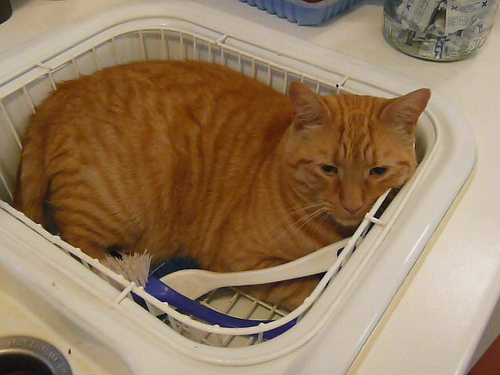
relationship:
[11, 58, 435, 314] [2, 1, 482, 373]
cat in sink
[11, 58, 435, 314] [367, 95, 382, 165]
cat has stripe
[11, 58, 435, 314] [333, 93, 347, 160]
cat has stripe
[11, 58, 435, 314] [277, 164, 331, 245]
cat has stripe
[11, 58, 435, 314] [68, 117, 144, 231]
cat has stripe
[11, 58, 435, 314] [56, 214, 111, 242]
cat has stripe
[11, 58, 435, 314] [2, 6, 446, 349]
cat in sink rack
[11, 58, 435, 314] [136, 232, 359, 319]
cat rests beside dish scrubber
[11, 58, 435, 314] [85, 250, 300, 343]
cat rests beside dish scrubber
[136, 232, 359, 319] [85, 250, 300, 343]
dish scrubber rests beside dish scrubber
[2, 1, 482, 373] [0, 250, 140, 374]
sink has left side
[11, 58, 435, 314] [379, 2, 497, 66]
cat rests beside jar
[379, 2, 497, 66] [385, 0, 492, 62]
jar filled with inscrutable papers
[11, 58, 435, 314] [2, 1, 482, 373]
cat rests in sink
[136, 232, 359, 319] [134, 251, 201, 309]
dish scrubber has bristles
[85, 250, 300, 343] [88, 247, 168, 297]
dish scrubber has bristles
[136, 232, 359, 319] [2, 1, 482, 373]
dish scrubber in sink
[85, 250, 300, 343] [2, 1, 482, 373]
dish scrubber in sink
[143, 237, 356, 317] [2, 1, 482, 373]
dish scrubber in sink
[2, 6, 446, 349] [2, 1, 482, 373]
sink rack in sink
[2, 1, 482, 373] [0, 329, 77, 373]
sink has drain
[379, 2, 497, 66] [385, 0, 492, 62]
jar contains wipes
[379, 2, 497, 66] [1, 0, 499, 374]
jar on counter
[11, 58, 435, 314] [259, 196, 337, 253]
cat has whiskers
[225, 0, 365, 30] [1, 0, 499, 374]
container on counter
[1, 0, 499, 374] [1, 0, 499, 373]
counter has counter top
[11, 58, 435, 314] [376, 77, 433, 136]
cat has ear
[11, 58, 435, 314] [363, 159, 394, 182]
cat has eye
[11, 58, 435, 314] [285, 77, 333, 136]
cat has ear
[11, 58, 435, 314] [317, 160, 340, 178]
cat has eye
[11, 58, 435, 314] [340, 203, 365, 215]
cat has nose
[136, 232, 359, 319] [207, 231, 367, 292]
dish scrubber has long handle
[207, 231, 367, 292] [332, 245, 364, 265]
long handle has end hole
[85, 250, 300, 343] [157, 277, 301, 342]
dish scrubber has long handle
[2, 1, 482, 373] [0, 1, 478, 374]
sink has right side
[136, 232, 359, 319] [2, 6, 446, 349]
dish scrubber inside sink rack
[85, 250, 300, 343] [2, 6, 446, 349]
dish scrubber inside sink rack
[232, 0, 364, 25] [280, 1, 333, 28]
container has edge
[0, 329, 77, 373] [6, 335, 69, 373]
drain has writing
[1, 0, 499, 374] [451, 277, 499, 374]
counter has edge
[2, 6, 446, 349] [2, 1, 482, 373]
sink rack rests on sink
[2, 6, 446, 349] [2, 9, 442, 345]
sink rack has fluted edges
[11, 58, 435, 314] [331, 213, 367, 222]
cat has mouth